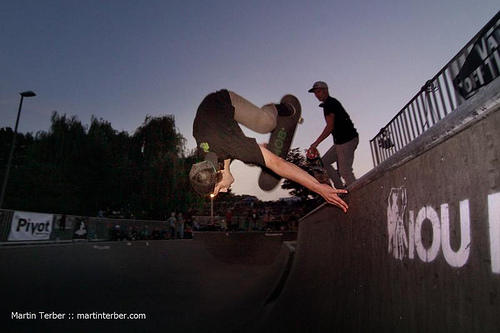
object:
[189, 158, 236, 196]
head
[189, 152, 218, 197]
hat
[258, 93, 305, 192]
skateboard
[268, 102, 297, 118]
feet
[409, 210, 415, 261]
letters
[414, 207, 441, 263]
letters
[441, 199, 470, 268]
letters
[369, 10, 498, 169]
rail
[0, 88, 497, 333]
ramp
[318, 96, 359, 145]
shirt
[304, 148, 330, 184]
skateboard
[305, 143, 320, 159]
hand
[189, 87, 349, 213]
boy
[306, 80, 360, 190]
boy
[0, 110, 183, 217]
trees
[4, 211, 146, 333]
park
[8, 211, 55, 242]
banner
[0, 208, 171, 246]
fence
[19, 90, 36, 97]
light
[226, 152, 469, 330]
park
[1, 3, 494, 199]
sky